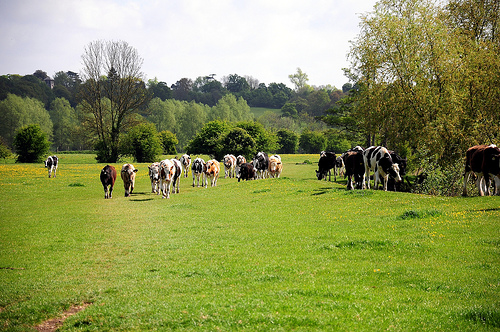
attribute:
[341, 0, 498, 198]
tree — large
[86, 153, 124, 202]
cow — brown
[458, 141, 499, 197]
cow — eating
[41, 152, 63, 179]
cow — black, white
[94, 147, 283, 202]
cow — black, white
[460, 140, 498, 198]
cow — black, white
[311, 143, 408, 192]
cow — black, white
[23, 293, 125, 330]
dirt — brown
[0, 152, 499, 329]
grass — dark green, green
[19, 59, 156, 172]
tree — old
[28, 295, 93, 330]
bare patch — brown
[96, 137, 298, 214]
cows — walking 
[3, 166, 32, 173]
flowers — yellow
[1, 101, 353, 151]
bushes — green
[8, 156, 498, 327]
field — grass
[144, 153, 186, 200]
cows — white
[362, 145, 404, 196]
cow — black and white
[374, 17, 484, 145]
leaves — green